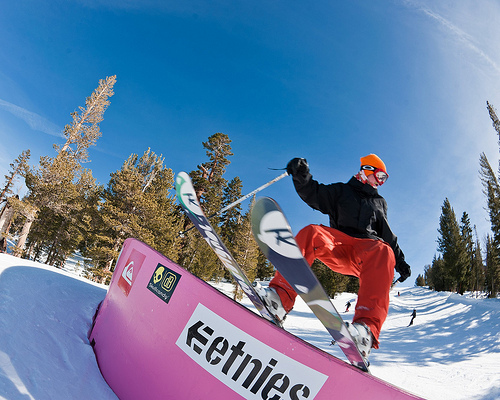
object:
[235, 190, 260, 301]
trees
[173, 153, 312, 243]
ski pole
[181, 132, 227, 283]
tree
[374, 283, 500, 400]
snow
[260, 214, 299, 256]
sign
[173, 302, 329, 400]
advertising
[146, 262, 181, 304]
advertising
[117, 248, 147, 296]
advertising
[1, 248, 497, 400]
slope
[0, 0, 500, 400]
scene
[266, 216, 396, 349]
pants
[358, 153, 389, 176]
hat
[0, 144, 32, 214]
tree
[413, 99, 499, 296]
pinetrees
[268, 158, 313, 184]
gloves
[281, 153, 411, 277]
jacket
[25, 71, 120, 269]
tree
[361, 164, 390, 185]
goggles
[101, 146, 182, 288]
tree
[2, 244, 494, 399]
field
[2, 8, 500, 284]
sky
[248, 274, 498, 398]
ground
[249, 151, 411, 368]
skier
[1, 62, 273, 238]
field